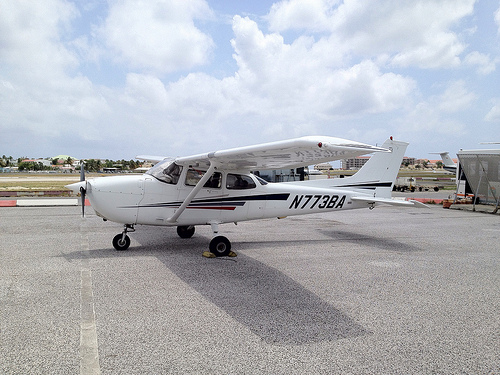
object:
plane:
[62, 131, 432, 256]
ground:
[2, 194, 498, 374]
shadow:
[60, 223, 428, 344]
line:
[77, 213, 105, 374]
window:
[226, 173, 256, 190]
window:
[185, 169, 222, 189]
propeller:
[79, 162, 87, 216]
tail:
[353, 138, 431, 215]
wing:
[176, 134, 394, 171]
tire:
[112, 233, 129, 250]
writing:
[290, 193, 348, 209]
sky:
[56, 0, 500, 128]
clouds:
[0, 0, 499, 153]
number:
[289, 195, 346, 209]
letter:
[289, 194, 305, 209]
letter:
[335, 195, 347, 208]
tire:
[209, 236, 231, 257]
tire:
[176, 224, 195, 238]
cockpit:
[146, 159, 182, 185]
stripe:
[168, 205, 237, 211]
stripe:
[120, 200, 246, 208]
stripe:
[153, 192, 291, 201]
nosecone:
[65, 181, 87, 193]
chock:
[230, 249, 237, 256]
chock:
[203, 251, 216, 258]